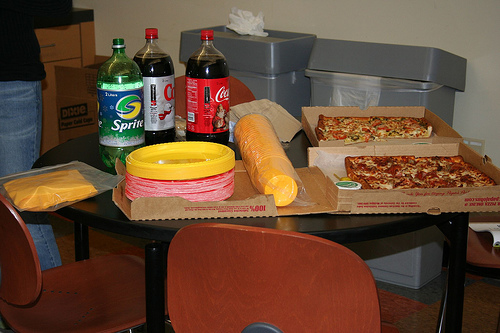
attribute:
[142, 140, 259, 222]
plates — pink and yellow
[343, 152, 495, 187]
pizza — one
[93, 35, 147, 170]
green bottle — soda, open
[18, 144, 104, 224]
napkins — yellow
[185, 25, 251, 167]
coke — diet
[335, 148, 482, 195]
pizza — large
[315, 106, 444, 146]
pizza — large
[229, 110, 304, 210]
water glass — yellow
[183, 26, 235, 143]
bottle — 2-liter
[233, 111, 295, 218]
cups — plastic, yellow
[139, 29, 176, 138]
soda bottle — labeled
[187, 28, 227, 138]
bottle — big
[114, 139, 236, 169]
plate — yellow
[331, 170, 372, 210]
butter — garlic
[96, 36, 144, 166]
two liter — uncapped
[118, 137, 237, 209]
plates — red and yellow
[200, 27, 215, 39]
cap — red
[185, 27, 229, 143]
soda — bottled, labled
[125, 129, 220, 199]
plates — piled up, stacked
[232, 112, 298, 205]
stacked cups — yellow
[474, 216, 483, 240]
paper towel — white